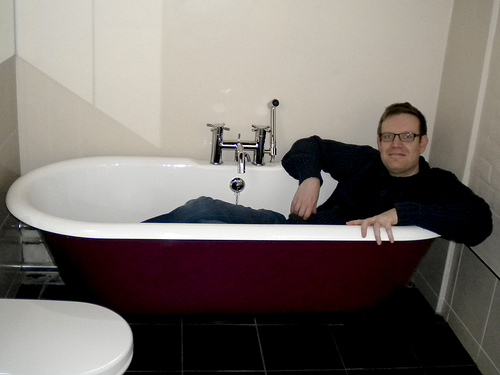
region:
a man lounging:
[132, 100, 494, 242]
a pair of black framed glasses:
[376, 129, 425, 146]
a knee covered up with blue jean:
[147, 197, 284, 225]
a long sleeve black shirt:
[284, 137, 494, 246]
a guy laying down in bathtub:
[8, 101, 493, 324]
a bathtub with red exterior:
[9, 157, 440, 319]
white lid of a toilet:
[1, 296, 136, 373]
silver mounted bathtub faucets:
[204, 117, 272, 172]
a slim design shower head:
[266, 97, 282, 160]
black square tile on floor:
[0, 189, 481, 374]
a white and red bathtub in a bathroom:
[5, 153, 440, 310]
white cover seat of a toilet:
[1, 292, 131, 372]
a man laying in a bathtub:
[135, 102, 495, 248]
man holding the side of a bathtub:
[345, 205, 398, 247]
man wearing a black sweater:
[281, 135, 494, 251]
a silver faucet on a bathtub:
[209, 120, 273, 177]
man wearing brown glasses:
[377, 129, 420, 143]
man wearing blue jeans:
[143, 194, 291, 234]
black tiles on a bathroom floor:
[12, 268, 482, 374]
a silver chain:
[234, 193, 240, 205]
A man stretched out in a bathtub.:
[140, 101, 497, 251]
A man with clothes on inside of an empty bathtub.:
[7, 99, 497, 329]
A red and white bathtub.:
[11, 152, 448, 312]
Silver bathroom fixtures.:
[190, 93, 280, 184]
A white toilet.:
[0, 294, 138, 374]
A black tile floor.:
[15, 262, 487, 372]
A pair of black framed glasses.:
[378, 130, 426, 145]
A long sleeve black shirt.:
[285, 131, 494, 262]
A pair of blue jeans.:
[135, 195, 298, 236]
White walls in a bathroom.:
[2, 2, 497, 370]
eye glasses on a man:
[377, 129, 423, 144]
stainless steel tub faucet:
[209, 121, 278, 169]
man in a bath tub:
[8, 64, 496, 304]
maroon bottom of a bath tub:
[169, 251, 278, 298]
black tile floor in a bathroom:
[232, 322, 296, 364]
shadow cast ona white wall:
[122, 36, 249, 127]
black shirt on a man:
[297, 115, 484, 260]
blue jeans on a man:
[173, 193, 235, 222]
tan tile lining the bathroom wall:
[437, 257, 495, 309]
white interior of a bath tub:
[47, 172, 92, 207]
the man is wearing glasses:
[369, 124, 429, 146]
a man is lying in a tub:
[4, 45, 484, 302]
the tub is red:
[181, 252, 303, 299]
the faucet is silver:
[202, 90, 286, 182]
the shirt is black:
[334, 153, 373, 225]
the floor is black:
[207, 310, 373, 365]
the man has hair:
[385, 101, 417, 116]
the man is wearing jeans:
[167, 193, 259, 221]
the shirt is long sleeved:
[298, 135, 353, 204]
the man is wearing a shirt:
[295, 173, 462, 224]